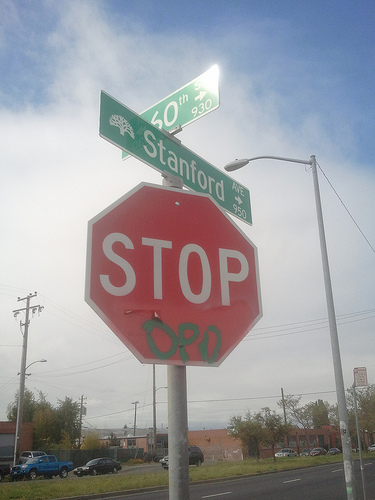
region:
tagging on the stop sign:
[147, 318, 225, 361]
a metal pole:
[163, 374, 202, 496]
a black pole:
[74, 458, 122, 475]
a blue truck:
[17, 456, 71, 474]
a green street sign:
[109, 135, 234, 180]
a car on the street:
[270, 445, 301, 456]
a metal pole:
[309, 174, 332, 250]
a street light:
[224, 160, 252, 172]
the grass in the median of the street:
[215, 459, 255, 472]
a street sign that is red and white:
[350, 366, 369, 386]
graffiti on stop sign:
[148, 311, 234, 360]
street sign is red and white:
[123, 204, 261, 354]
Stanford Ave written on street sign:
[155, 124, 232, 185]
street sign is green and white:
[123, 125, 290, 206]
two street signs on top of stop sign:
[92, 66, 255, 182]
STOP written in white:
[117, 231, 231, 329]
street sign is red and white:
[350, 362, 373, 396]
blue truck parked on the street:
[10, 443, 77, 476]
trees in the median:
[242, 417, 295, 465]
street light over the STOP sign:
[221, 119, 332, 220]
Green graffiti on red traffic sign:
[143, 309, 226, 363]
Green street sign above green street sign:
[122, 62, 220, 161]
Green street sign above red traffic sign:
[99, 83, 252, 223]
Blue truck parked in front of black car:
[10, 451, 74, 480]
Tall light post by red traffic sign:
[223, 149, 360, 498]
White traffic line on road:
[281, 475, 302, 483]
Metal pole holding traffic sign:
[160, 172, 189, 499]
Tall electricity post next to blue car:
[9, 287, 47, 473]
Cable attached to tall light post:
[314, 159, 374, 256]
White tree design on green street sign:
[105, 111, 137, 145]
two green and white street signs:
[90, 45, 283, 196]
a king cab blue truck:
[2, 448, 72, 488]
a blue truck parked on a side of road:
[11, 451, 79, 483]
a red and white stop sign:
[83, 201, 281, 312]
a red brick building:
[204, 421, 343, 467]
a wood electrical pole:
[4, 287, 43, 454]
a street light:
[0, 350, 57, 375]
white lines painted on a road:
[200, 464, 339, 498]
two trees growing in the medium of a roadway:
[218, 409, 304, 484]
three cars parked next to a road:
[21, 437, 199, 482]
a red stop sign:
[83, 184, 262, 366]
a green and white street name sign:
[95, 86, 249, 222]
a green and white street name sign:
[120, 61, 220, 157]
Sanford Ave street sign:
[96, 89, 251, 225]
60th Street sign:
[122, 65, 220, 159]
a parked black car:
[75, 457, 121, 476]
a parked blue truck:
[7, 454, 73, 479]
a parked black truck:
[159, 446, 202, 465]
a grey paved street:
[96, 450, 371, 496]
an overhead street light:
[223, 150, 363, 497]